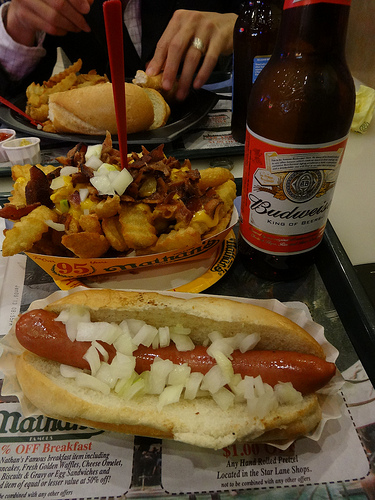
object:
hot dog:
[13, 305, 335, 395]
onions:
[67, 311, 291, 412]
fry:
[1, 206, 56, 260]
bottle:
[237, 0, 355, 284]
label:
[242, 124, 349, 255]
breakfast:
[37, 437, 95, 459]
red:
[77, 443, 85, 453]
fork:
[99, 0, 131, 174]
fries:
[0, 139, 235, 259]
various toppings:
[49, 151, 205, 210]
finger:
[177, 23, 209, 100]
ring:
[193, 37, 206, 53]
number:
[52, 260, 95, 278]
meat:
[264, 349, 341, 385]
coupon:
[1, 396, 141, 500]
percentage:
[0, 442, 18, 468]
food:
[0, 154, 344, 461]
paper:
[0, 402, 375, 498]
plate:
[0, 285, 344, 454]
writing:
[246, 194, 334, 225]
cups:
[2, 135, 43, 170]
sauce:
[0, 135, 39, 150]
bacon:
[2, 170, 56, 224]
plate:
[58, 194, 237, 296]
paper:
[3, 138, 41, 167]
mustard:
[7, 135, 38, 151]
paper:
[0, 130, 15, 157]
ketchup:
[0, 127, 15, 146]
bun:
[0, 288, 337, 453]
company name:
[0, 406, 114, 450]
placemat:
[0, 177, 375, 483]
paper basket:
[22, 186, 240, 280]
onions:
[66, 143, 132, 205]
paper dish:
[0, 280, 345, 453]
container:
[24, 165, 240, 287]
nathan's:
[102, 238, 227, 274]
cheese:
[129, 167, 157, 193]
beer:
[237, 0, 356, 284]